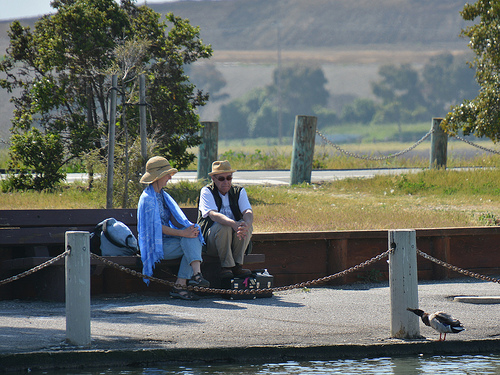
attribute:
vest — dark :
[226, 190, 238, 209]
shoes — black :
[171, 266, 216, 306]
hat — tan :
[130, 149, 177, 199]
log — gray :
[29, 224, 290, 324]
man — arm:
[196, 158, 255, 279]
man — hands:
[192, 154, 254, 281]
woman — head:
[134, 153, 209, 304]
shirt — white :
[221, 198, 233, 217]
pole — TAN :
[429, 118, 454, 168]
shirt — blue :
[125, 182, 190, 287]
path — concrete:
[0, 276, 499, 353]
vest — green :
[199, 187, 254, 231]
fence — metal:
[316, 129, 432, 169]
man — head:
[205, 156, 257, 280]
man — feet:
[200, 165, 267, 306]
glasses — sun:
[216, 167, 234, 184]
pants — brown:
[207, 220, 252, 266]